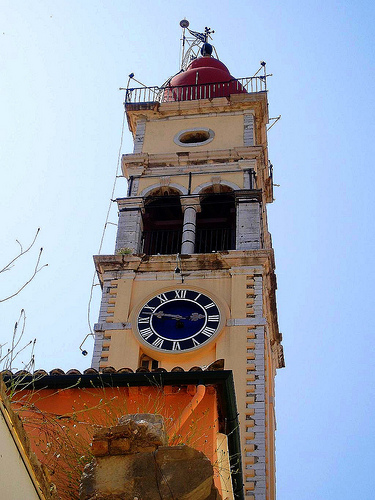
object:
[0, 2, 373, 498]
sky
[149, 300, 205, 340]
face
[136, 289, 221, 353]
clock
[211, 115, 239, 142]
wall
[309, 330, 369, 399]
clouds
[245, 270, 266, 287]
brick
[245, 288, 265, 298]
brick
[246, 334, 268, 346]
brick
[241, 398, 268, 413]
brick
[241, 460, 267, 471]
brick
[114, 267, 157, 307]
wall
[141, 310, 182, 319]
minute hand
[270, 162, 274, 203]
pipe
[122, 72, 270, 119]
roof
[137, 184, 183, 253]
arch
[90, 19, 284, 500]
building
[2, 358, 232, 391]
roof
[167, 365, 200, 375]
roof shingles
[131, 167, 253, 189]
wall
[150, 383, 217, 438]
wall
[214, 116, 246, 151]
wall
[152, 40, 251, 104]
dome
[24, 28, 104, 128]
clouds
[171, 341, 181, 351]
numeral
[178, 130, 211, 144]
window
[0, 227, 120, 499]
branches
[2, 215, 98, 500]
tree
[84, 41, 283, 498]
tower